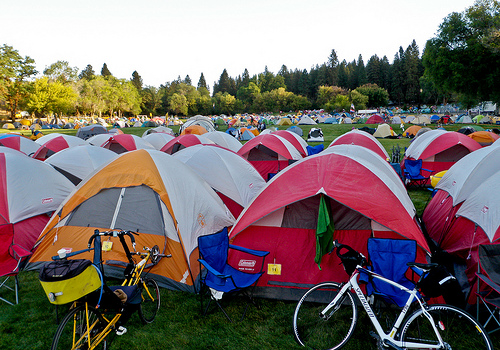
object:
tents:
[396, 128, 487, 189]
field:
[7, 103, 499, 346]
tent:
[14, 145, 242, 302]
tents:
[364, 114, 386, 124]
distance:
[3, 4, 499, 124]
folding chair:
[192, 226, 269, 322]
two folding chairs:
[190, 226, 436, 337]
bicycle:
[289, 240, 493, 348]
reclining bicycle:
[35, 226, 172, 350]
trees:
[1, 45, 49, 121]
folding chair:
[1, 223, 30, 308]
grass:
[5, 272, 495, 348]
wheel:
[290, 279, 359, 348]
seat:
[404, 259, 440, 271]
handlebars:
[335, 241, 367, 278]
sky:
[3, 1, 487, 92]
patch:
[164, 300, 241, 348]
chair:
[403, 158, 436, 192]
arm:
[420, 168, 435, 178]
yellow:
[64, 281, 87, 296]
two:
[375, 122, 418, 138]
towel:
[314, 190, 339, 270]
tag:
[266, 263, 282, 275]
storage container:
[39, 255, 105, 306]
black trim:
[19, 246, 36, 272]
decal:
[237, 259, 256, 267]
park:
[2, 0, 496, 345]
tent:
[195, 147, 436, 316]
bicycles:
[37, 226, 173, 345]